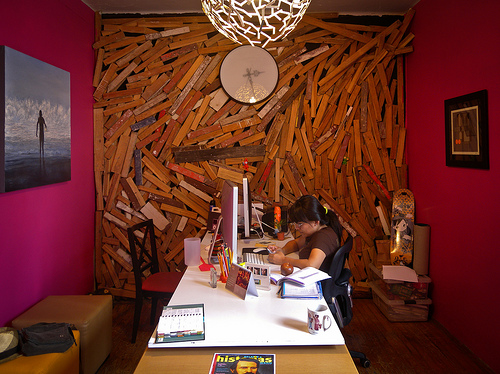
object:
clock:
[219, 45, 277, 104]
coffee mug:
[308, 304, 331, 334]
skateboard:
[389, 188, 414, 267]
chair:
[126, 218, 182, 340]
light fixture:
[201, 0, 310, 46]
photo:
[2, 44, 74, 191]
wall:
[2, 1, 98, 329]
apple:
[281, 261, 294, 277]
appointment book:
[155, 304, 205, 345]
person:
[263, 192, 343, 281]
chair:
[326, 238, 351, 325]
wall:
[91, 14, 417, 298]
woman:
[266, 195, 345, 279]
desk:
[135, 223, 357, 373]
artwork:
[445, 88, 488, 168]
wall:
[405, 1, 498, 366]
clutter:
[365, 188, 436, 323]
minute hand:
[244, 69, 265, 75]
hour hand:
[246, 71, 256, 94]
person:
[36, 110, 48, 162]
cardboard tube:
[413, 221, 429, 277]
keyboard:
[241, 250, 266, 273]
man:
[228, 358, 261, 373]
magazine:
[209, 352, 278, 373]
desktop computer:
[222, 180, 282, 271]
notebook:
[269, 266, 331, 287]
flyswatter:
[199, 253, 213, 270]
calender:
[224, 261, 260, 298]